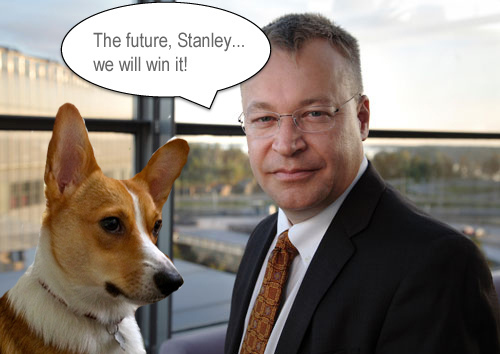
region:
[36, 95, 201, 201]
long and pointy ears of dog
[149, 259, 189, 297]
black nose of dog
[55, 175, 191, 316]
head of dog is white and brown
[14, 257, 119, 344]
neck of dog is white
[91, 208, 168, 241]
eyes of dog are black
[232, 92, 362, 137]
glasses on face of man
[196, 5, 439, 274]
man has short hair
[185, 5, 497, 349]
mas wears a black suit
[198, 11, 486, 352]
man has white shirt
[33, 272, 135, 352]
dog has collar with tag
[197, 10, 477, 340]
this is a man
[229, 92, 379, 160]
a pair of glasses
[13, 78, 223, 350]
this is a dog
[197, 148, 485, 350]
man wearing a suit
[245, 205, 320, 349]
man wearing a tie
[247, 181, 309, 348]
the tie is brown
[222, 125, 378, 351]
man wearing a white shirt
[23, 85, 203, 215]
dogs ears are up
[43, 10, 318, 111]
a white conversation bubble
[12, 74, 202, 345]
the dog is brown and white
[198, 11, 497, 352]
The man is wearing glasses.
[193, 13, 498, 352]
The man is wearing a tie.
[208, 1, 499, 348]
The man is wearing a suit jacket.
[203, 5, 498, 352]
The man is smiling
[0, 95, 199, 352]
The dog is brown and white.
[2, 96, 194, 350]
The dog is wearing a collar.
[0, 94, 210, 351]
The dog is wearing dog tags.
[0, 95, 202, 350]
The dog is alert.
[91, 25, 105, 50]
The letter is black.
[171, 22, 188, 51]
The letter is black.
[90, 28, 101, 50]
The letter is black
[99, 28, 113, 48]
The letter is black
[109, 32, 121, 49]
The letter is black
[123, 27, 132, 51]
The letter is black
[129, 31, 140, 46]
The letter is black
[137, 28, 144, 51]
The letter is black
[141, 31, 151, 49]
The letter is black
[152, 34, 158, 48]
The letter is black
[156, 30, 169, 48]
The letter is black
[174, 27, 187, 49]
The letter is black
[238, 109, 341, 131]
man is wearing glasses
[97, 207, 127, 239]
the dogs eye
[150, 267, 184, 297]
the dogs nose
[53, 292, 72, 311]
the collar on the dog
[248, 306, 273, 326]
the man is wearing a tie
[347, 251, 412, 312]
the suit the man is wearing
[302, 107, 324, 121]
the mans left eye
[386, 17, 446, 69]
clouds in the sky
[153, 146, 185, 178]
left ear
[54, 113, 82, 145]
right ear